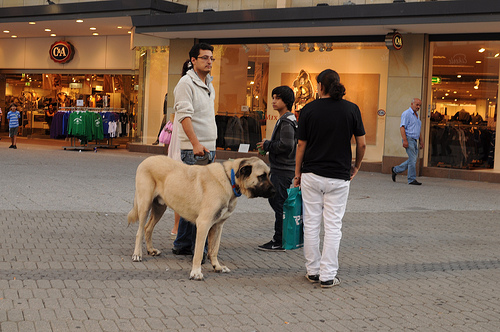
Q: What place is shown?
A: It is a sidewalk.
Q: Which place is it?
A: It is a sidewalk.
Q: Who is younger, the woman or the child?
A: The child is younger than the woman.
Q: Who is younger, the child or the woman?
A: The child is younger than the woman.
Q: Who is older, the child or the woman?
A: The woman is older than the child.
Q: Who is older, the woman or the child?
A: The woman is older than the child.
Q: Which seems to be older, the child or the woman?
A: The woman is older than the child.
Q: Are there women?
A: Yes, there is a woman.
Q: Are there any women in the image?
A: Yes, there is a woman.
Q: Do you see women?
A: Yes, there is a woman.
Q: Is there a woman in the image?
A: Yes, there is a woman.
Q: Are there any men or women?
A: Yes, there is a woman.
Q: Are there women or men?
A: Yes, there is a woman.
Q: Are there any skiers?
A: No, there are no skiers.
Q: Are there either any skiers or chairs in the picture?
A: No, there are no skiers or chairs.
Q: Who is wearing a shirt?
A: The woman is wearing a shirt.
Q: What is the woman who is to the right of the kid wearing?
A: The woman is wearing a shirt.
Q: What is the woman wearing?
A: The woman is wearing a shirt.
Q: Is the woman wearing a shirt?
A: Yes, the woman is wearing a shirt.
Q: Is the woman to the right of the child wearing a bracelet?
A: No, the woman is wearing a shirt.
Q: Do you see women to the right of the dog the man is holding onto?
A: Yes, there is a woman to the right of the dog.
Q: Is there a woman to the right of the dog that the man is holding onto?
A: Yes, there is a woman to the right of the dog.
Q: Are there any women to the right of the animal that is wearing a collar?
A: Yes, there is a woman to the right of the dog.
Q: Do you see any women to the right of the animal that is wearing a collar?
A: Yes, there is a woman to the right of the dog.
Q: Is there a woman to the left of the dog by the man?
A: No, the woman is to the right of the dog.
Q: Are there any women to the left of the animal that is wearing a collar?
A: No, the woman is to the right of the dog.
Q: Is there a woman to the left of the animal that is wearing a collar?
A: No, the woman is to the right of the dog.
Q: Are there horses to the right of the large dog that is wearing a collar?
A: No, there is a woman to the right of the dog.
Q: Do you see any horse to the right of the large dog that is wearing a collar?
A: No, there is a woman to the right of the dog.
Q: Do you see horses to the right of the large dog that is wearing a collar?
A: No, there is a woman to the right of the dog.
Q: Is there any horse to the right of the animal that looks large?
A: No, there is a woman to the right of the dog.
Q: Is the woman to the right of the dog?
A: Yes, the woman is to the right of the dog.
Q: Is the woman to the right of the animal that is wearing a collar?
A: Yes, the woman is to the right of the dog.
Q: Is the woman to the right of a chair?
A: No, the woman is to the right of the dog.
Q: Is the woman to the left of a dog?
A: No, the woman is to the right of a dog.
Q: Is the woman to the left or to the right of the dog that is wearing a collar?
A: The woman is to the right of the dog.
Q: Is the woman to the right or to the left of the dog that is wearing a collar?
A: The woman is to the right of the dog.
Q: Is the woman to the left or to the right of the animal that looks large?
A: The woman is to the right of the dog.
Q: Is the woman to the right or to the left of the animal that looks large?
A: The woman is to the right of the dog.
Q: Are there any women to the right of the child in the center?
A: Yes, there is a woman to the right of the kid.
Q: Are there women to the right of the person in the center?
A: Yes, there is a woman to the right of the kid.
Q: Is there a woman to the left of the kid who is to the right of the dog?
A: No, the woman is to the right of the child.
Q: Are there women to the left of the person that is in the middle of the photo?
A: No, the woman is to the right of the child.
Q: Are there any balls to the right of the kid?
A: No, there is a woman to the right of the kid.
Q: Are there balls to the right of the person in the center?
A: No, there is a woman to the right of the kid.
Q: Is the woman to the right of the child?
A: Yes, the woman is to the right of the child.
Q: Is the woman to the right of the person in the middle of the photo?
A: Yes, the woman is to the right of the child.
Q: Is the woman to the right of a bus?
A: No, the woman is to the right of the child.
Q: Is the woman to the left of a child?
A: No, the woman is to the right of a child.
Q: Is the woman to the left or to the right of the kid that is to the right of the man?
A: The woman is to the right of the child.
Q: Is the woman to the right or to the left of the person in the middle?
A: The woman is to the right of the child.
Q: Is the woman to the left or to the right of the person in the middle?
A: The woman is to the right of the child.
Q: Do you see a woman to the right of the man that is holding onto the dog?
A: Yes, there is a woman to the right of the man.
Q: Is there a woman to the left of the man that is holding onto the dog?
A: No, the woman is to the right of the man.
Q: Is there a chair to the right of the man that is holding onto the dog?
A: No, there is a woman to the right of the man.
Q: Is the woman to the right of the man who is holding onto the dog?
A: Yes, the woman is to the right of the man.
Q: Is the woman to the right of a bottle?
A: No, the woman is to the right of the man.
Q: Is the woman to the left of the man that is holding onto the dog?
A: No, the woman is to the right of the man.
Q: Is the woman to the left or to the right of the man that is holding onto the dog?
A: The woman is to the right of the man.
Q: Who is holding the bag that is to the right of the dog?
A: The woman is holding the bag.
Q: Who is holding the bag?
A: The woman is holding the bag.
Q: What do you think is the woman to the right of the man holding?
A: The woman is holding the bag.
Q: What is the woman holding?
A: The woman is holding the bag.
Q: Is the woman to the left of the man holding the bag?
A: Yes, the woman is holding the bag.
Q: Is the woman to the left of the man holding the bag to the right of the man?
A: Yes, the woman is holding the bag.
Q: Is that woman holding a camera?
A: No, the woman is holding the bag.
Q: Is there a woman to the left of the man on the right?
A: Yes, there is a woman to the left of the man.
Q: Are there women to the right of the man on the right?
A: No, the woman is to the left of the man.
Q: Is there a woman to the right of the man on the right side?
A: No, the woman is to the left of the man.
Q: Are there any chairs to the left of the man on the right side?
A: No, there is a woman to the left of the man.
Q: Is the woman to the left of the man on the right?
A: Yes, the woman is to the left of the man.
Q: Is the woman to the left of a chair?
A: No, the woman is to the left of the man.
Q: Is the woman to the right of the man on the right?
A: No, the woman is to the left of the man.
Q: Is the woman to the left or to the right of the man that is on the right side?
A: The woman is to the left of the man.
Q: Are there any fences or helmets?
A: No, there are no fences or helmets.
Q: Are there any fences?
A: No, there are no fences.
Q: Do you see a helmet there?
A: No, there are no helmets.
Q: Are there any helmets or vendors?
A: No, there are no helmets or vendors.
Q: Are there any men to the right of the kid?
A: Yes, there is a man to the right of the kid.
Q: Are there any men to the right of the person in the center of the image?
A: Yes, there is a man to the right of the kid.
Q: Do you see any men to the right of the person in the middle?
A: Yes, there is a man to the right of the kid.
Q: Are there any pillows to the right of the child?
A: No, there is a man to the right of the child.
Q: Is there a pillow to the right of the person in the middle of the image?
A: No, there is a man to the right of the child.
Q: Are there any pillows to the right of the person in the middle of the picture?
A: No, there is a man to the right of the child.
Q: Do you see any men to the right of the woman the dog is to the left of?
A: Yes, there is a man to the right of the woman.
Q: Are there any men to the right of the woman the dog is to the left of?
A: Yes, there is a man to the right of the woman.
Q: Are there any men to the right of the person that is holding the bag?
A: Yes, there is a man to the right of the woman.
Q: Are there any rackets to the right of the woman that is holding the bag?
A: No, there is a man to the right of the woman.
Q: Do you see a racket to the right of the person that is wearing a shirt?
A: No, there is a man to the right of the woman.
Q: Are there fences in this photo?
A: No, there are no fences.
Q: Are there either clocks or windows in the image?
A: Yes, there is a window.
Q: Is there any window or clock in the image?
A: Yes, there is a window.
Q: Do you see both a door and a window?
A: No, there is a window but no doors.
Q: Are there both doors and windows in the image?
A: No, there is a window but no doors.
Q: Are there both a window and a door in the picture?
A: No, there is a window but no doors.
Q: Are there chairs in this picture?
A: No, there are no chairs.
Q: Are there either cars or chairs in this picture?
A: No, there are no chairs or cars.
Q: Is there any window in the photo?
A: Yes, there is a window.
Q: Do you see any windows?
A: Yes, there is a window.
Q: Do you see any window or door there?
A: Yes, there is a window.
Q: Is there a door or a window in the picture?
A: Yes, there is a window.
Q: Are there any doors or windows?
A: Yes, there is a window.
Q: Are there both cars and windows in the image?
A: No, there is a window but no cars.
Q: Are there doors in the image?
A: No, there are no doors.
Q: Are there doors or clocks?
A: No, there are no doors or clocks.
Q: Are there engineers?
A: No, there are no engineers.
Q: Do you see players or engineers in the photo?
A: No, there are no engineers or players.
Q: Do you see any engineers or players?
A: No, there are no engineers or players.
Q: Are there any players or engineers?
A: No, there are no engineers or players.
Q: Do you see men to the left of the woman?
A: Yes, there is a man to the left of the woman.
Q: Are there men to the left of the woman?
A: Yes, there is a man to the left of the woman.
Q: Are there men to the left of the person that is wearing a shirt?
A: Yes, there is a man to the left of the woman.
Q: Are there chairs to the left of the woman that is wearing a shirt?
A: No, there is a man to the left of the woman.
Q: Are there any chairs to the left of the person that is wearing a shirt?
A: No, there is a man to the left of the woman.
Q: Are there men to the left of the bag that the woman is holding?
A: Yes, there is a man to the left of the bag.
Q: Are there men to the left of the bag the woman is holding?
A: Yes, there is a man to the left of the bag.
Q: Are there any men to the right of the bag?
A: No, the man is to the left of the bag.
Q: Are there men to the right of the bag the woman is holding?
A: No, the man is to the left of the bag.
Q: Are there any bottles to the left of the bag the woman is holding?
A: No, there is a man to the left of the bag.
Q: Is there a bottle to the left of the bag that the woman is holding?
A: No, there is a man to the left of the bag.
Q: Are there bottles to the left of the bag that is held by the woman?
A: No, there is a man to the left of the bag.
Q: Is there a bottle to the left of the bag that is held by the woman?
A: No, there is a man to the left of the bag.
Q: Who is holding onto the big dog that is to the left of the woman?
A: The man is holding onto the dog.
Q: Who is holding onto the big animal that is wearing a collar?
A: The man is holding onto the dog.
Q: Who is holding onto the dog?
A: The man is holding onto the dog.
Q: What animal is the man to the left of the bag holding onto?
A: The man is holding onto the dog.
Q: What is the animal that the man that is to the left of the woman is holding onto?
A: The animal is a dog.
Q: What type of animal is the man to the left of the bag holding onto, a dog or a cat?
A: The man is holding onto a dog.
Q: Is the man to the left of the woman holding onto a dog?
A: Yes, the man is holding onto a dog.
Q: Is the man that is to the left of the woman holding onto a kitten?
A: No, the man is holding onto a dog.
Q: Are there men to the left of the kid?
A: Yes, there is a man to the left of the kid.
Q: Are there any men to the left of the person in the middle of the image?
A: Yes, there is a man to the left of the kid.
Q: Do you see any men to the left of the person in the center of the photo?
A: Yes, there is a man to the left of the kid.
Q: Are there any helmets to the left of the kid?
A: No, there is a man to the left of the kid.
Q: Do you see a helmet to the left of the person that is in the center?
A: No, there is a man to the left of the kid.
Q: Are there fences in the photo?
A: No, there are no fences.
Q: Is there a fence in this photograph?
A: No, there are no fences.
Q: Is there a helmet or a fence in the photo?
A: No, there are no fences or helmets.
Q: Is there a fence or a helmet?
A: No, there are no fences or helmets.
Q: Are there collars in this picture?
A: Yes, there is a collar.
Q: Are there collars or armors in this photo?
A: Yes, there is a collar.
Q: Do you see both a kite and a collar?
A: No, there is a collar but no kites.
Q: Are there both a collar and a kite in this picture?
A: No, there is a collar but no kites.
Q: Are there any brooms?
A: No, there are no brooms.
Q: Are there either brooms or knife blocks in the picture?
A: No, there are no brooms or knife blocks.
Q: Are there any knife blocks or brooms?
A: No, there are no brooms or knife blocks.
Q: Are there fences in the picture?
A: No, there are no fences.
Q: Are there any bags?
A: Yes, there is a bag.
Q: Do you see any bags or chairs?
A: Yes, there is a bag.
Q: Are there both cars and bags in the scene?
A: No, there is a bag but no cars.